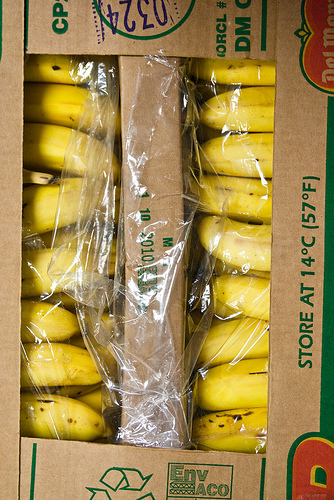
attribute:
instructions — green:
[279, 163, 320, 376]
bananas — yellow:
[199, 62, 272, 448]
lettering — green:
[298, 166, 319, 371]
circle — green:
[94, 6, 183, 41]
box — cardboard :
[1, 51, 25, 490]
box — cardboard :
[122, 47, 194, 450]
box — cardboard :
[272, 27, 331, 411]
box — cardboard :
[270, 32, 331, 495]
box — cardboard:
[269, 103, 330, 497]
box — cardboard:
[12, 432, 333, 495]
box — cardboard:
[1, 437, 332, 498]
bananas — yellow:
[193, 54, 264, 449]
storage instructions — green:
[278, 159, 330, 373]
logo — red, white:
[284, 25, 328, 88]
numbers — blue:
[87, 5, 164, 32]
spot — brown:
[205, 413, 255, 430]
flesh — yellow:
[202, 109, 265, 237]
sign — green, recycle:
[83, 469, 153, 493]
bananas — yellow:
[61, 142, 223, 315]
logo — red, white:
[290, 31, 314, 91]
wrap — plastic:
[88, 241, 207, 363]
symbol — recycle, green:
[72, 458, 122, 498]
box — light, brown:
[288, 384, 318, 417]